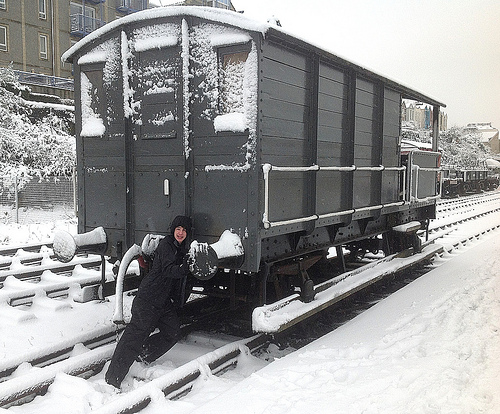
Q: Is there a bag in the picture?
A: No, there are no bags.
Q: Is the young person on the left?
A: Yes, the person is on the left of the image.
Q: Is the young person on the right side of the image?
A: No, the person is on the left of the image.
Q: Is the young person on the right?
A: No, the person is on the left of the image.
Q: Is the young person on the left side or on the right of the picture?
A: The person is on the left of the image.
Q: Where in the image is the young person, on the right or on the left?
A: The person is on the left of the image.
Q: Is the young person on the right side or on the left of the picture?
A: The person is on the left of the image.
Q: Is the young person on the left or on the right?
A: The person is on the left of the image.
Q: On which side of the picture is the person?
A: The person is on the left of the image.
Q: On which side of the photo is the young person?
A: The person is on the left of the image.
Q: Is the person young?
A: Yes, the person is young.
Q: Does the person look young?
A: Yes, the person is young.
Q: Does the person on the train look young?
A: Yes, the person is young.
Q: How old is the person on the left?
A: The person is young.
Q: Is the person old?
A: No, the person is young.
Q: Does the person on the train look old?
A: No, the person is young.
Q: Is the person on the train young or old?
A: The person is young.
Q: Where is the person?
A: The person is on the train.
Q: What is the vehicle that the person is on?
A: The vehicle is a train.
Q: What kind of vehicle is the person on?
A: The person is on the train.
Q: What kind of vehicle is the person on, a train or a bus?
A: The person is on a train.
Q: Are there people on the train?
A: Yes, there is a person on the train.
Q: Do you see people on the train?
A: Yes, there is a person on the train.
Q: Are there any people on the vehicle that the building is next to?
A: Yes, there is a person on the train.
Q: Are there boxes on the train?
A: No, there is a person on the train.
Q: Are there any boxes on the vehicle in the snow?
A: No, there is a person on the train.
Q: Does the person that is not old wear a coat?
A: Yes, the person wears a coat.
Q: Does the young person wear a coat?
A: Yes, the person wears a coat.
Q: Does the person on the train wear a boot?
A: No, the person wears a coat.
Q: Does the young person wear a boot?
A: No, the person wears a coat.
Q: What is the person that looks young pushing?
A: The person is pushing the train.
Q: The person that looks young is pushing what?
A: The person is pushing the train.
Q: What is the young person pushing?
A: The person is pushing the train.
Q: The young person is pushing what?
A: The person is pushing the train.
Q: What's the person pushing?
A: The person is pushing the train.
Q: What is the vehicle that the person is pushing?
A: The vehicle is a train.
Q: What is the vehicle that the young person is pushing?
A: The vehicle is a train.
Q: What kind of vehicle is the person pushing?
A: The person is pushing the train.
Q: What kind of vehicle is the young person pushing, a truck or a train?
A: The person is pushing a train.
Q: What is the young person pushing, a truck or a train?
A: The person is pushing a train.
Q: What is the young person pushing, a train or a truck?
A: The person is pushing a train.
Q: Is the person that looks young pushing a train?
A: Yes, the person is pushing a train.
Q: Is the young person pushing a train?
A: Yes, the person is pushing a train.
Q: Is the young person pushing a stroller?
A: No, the person is pushing a train.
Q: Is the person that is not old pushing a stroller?
A: No, the person is pushing a train.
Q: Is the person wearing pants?
A: Yes, the person is wearing pants.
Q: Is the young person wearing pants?
A: Yes, the person is wearing pants.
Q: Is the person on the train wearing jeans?
A: No, the person is wearing pants.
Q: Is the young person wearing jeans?
A: No, the person is wearing pants.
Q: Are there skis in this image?
A: No, there are no skis.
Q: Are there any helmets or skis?
A: No, there are no skis or helmets.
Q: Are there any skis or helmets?
A: No, there are no skis or helmets.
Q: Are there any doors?
A: Yes, there is a door.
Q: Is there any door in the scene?
A: Yes, there is a door.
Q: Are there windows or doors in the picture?
A: Yes, there is a door.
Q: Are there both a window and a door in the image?
A: Yes, there are both a door and a window.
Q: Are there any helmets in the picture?
A: No, there are no helmets.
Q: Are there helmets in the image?
A: No, there are no helmets.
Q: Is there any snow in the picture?
A: Yes, there is snow.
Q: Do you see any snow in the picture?
A: Yes, there is snow.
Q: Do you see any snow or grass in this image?
A: Yes, there is snow.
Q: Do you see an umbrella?
A: No, there are no umbrellas.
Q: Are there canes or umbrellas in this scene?
A: No, there are no umbrellas or canes.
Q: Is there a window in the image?
A: Yes, there is a window.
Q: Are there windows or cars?
A: Yes, there is a window.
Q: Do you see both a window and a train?
A: Yes, there are both a window and a train.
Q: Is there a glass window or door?
A: Yes, there is a glass window.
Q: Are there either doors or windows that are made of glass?
A: Yes, the window is made of glass.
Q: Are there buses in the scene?
A: No, there are no buses.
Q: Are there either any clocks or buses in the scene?
A: No, there are no buses or clocks.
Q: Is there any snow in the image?
A: Yes, there is snow.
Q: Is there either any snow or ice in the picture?
A: Yes, there is snow.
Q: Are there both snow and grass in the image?
A: No, there is snow but no grass.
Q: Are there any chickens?
A: No, there are no chickens.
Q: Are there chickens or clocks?
A: No, there are no chickens or clocks.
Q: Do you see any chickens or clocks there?
A: No, there are no chickens or clocks.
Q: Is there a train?
A: Yes, there is a train.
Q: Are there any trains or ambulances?
A: Yes, there is a train.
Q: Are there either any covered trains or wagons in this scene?
A: Yes, there is a covered train.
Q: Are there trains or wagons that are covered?
A: Yes, the train is covered.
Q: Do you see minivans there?
A: No, there are no minivans.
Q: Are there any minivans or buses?
A: No, there are no minivans or buses.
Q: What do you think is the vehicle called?
A: The vehicle is a train.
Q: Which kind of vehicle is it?
A: The vehicle is a train.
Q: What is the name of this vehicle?
A: That is a train.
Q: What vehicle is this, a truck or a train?
A: That is a train.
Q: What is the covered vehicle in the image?
A: The vehicle is a train.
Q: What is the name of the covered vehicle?
A: The vehicle is a train.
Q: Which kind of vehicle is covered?
A: The vehicle is a train.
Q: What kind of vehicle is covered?
A: The vehicle is a train.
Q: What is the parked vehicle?
A: The vehicle is a train.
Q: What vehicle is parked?
A: The vehicle is a train.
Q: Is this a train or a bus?
A: This is a train.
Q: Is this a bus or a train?
A: This is a train.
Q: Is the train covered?
A: Yes, the train is covered.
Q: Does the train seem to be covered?
A: Yes, the train is covered.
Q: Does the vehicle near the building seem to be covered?
A: Yes, the train is covered.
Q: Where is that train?
A: The train is in the snow.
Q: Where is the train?
A: The train is in the snow.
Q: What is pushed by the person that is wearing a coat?
A: The train is pushed by the person.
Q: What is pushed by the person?
A: The train is pushed by the person.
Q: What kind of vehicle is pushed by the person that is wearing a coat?
A: The vehicle is a train.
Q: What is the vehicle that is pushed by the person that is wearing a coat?
A: The vehicle is a train.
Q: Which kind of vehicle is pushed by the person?
A: The vehicle is a train.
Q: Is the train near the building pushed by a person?
A: Yes, the train is pushed by a person.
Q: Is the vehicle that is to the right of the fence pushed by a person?
A: Yes, the train is pushed by a person.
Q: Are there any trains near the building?
A: Yes, there is a train near the building.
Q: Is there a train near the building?
A: Yes, there is a train near the building.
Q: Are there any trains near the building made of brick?
A: Yes, there is a train near the building.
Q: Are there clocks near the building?
A: No, there is a train near the building.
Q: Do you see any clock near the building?
A: No, there is a train near the building.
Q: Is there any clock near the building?
A: No, there is a train near the building.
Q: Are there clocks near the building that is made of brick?
A: No, there is a train near the building.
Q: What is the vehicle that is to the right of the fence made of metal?
A: The vehicle is a train.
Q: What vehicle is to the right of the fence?
A: The vehicle is a train.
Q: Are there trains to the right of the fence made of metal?
A: Yes, there is a train to the right of the fence.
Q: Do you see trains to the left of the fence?
A: No, the train is to the right of the fence.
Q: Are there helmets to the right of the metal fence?
A: No, there is a train to the right of the fence.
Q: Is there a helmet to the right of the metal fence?
A: No, there is a train to the right of the fence.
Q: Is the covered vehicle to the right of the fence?
A: Yes, the train is to the right of the fence.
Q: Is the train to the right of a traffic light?
A: No, the train is to the right of the fence.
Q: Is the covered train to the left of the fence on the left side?
A: No, the train is to the right of the fence.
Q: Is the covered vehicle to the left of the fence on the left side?
A: No, the train is to the right of the fence.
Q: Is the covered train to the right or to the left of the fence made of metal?
A: The train is to the right of the fence.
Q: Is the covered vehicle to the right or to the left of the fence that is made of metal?
A: The train is to the right of the fence.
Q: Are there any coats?
A: Yes, there is a coat.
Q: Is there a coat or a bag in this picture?
A: Yes, there is a coat.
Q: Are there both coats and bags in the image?
A: No, there is a coat but no bags.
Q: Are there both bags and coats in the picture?
A: No, there is a coat but no bags.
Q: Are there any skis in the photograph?
A: No, there are no skis.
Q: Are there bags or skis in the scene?
A: No, there are no skis or bags.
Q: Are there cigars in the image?
A: No, there are no cigars.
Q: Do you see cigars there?
A: No, there are no cigars.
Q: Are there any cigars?
A: No, there are no cigars.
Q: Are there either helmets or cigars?
A: No, there are no cigars or helmets.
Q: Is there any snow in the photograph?
A: Yes, there is snow.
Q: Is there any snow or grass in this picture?
A: Yes, there is snow.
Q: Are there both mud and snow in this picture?
A: No, there is snow but no mud.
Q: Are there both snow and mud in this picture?
A: No, there is snow but no mud.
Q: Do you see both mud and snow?
A: No, there is snow but no mud.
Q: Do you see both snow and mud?
A: No, there is snow but no mud.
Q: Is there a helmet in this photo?
A: No, there are no helmets.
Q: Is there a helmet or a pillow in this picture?
A: No, there are no helmets or pillows.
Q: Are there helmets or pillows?
A: No, there are no helmets or pillows.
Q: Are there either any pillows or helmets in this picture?
A: No, there are no helmets or pillows.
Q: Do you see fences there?
A: Yes, there is a fence.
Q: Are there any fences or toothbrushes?
A: Yes, there is a fence.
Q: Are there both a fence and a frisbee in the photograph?
A: No, there is a fence but no frisbees.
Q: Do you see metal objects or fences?
A: Yes, there is a metal fence.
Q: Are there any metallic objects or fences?
A: Yes, there is a metal fence.